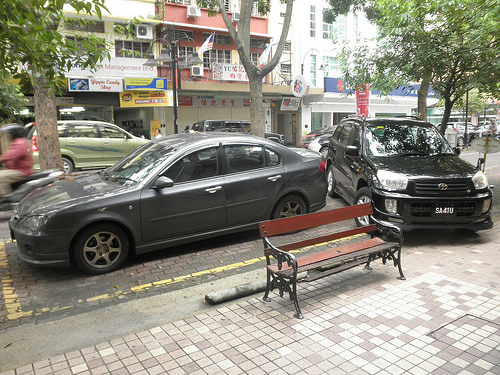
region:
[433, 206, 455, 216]
A front licence plate on a vehicle.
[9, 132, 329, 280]
A grey four-door car.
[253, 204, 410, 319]
A black and brown bench.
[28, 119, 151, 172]
A green SUV.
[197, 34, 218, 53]
A flag.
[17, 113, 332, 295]
A parked car.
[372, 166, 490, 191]
Headlights on a car.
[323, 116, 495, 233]
A black vehicle parked.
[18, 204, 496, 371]
Tiles on the ground.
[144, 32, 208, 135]
A black lamp post with multiple lights.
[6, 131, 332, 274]
a gray car parked behind a bench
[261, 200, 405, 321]
a bench beside the road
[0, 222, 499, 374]
a tile paved walkway beside a road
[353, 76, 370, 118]
a red banner hanging from a building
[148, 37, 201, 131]
a light pole next to a road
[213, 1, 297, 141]
a tree beside a gray car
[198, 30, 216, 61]
an American flag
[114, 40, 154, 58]
a row of windows in a building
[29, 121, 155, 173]
a silvery green minivan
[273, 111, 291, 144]
a door in a white building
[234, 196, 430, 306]
a wooden bench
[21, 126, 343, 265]
a grey car is parked in front of the black car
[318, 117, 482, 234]
the black car is behind the grey car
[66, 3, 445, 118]
there are buildings in the background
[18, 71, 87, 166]
this is the trees trunk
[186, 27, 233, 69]
this is an American Flag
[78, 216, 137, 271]
the grey cars tire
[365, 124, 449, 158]
the black cars windshield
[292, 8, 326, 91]
this building is yellow in color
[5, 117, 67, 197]
this person is on a motor bike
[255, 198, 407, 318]
black and brown metal bench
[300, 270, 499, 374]
patch of white and grey tiles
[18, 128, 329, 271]
grey compact car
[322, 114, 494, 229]
large black car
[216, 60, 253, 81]
white and red sign written in chinese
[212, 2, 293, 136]
brown tree with bare branches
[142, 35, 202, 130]
black lamp post with many lights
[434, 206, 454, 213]
license plate on the front of a black car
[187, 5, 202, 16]
white air conditioner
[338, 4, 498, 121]
leafy green tree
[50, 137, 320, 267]
grey car on sidewalk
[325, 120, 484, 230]
black hybrid next to grey car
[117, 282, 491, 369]
white and brown checked sidewalk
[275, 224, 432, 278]
red slats on bench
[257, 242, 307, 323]
metal sides on bench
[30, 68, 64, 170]
brown trunk on tree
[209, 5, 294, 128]
tall branched tree behind grey car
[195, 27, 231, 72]
red white and blue flag above grey car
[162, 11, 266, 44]
red frame next to flag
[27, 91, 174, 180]
light gold car behind grey car